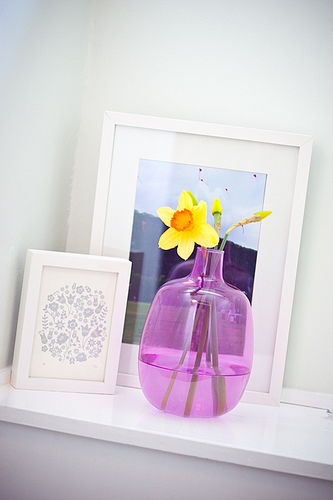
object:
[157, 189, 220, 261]
flower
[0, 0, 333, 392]
wall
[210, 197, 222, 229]
flower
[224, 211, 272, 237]
flower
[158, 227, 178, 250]
petal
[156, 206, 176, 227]
petal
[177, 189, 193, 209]
petal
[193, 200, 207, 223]
petal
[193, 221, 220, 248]
petal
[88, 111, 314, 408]
framed picture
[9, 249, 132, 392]
framed picture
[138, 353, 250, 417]
water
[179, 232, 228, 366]
stem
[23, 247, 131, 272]
top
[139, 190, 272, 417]
flower picture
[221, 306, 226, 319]
man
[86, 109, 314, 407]
frame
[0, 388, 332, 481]
mantle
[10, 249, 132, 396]
frame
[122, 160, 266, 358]
painting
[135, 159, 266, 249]
sky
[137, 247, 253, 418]
jar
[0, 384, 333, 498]
shelf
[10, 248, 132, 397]
items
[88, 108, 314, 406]
items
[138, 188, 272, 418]
items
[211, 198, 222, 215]
buds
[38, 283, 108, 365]
drawing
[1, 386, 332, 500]
counter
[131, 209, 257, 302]
hill